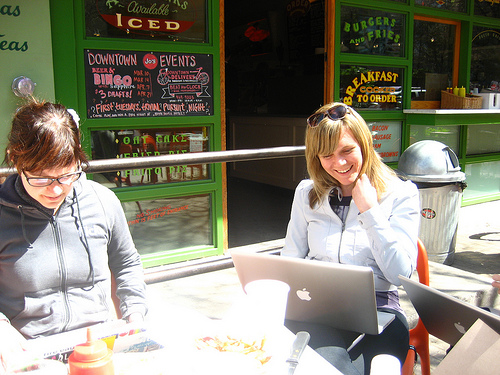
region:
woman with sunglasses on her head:
[308, 107, 365, 267]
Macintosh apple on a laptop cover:
[297, 287, 311, 300]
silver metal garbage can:
[426, 143, 453, 256]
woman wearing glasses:
[18, 112, 74, 316]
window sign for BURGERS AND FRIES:
[344, 15, 401, 46]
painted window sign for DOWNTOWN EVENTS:
[90, 54, 195, 65]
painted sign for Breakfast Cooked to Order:
[351, 72, 396, 102]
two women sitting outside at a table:
[19, 109, 396, 324]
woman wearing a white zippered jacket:
[308, 103, 388, 328]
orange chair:
[410, 325, 427, 367]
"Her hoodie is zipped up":
[7, 120, 143, 333]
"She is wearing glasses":
[8, 117, 102, 222]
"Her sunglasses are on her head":
[292, 83, 409, 252]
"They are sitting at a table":
[5, 82, 497, 373]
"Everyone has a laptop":
[7, 82, 498, 373]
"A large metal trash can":
[403, 123, 490, 267]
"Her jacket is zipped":
[271, 72, 459, 329]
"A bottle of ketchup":
[59, 323, 121, 373]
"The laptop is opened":
[221, 223, 418, 355]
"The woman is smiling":
[283, 103, 424, 258]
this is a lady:
[301, 107, 412, 267]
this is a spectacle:
[306, 106, 348, 118]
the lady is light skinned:
[358, 187, 370, 200]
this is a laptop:
[291, 265, 381, 322]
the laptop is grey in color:
[309, 268, 362, 330]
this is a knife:
[285, 334, 306, 374]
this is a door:
[221, 0, 331, 95]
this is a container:
[246, 277, 286, 319]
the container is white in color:
[258, 299, 276, 314]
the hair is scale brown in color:
[310, 127, 331, 141]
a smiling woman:
[268, 83, 457, 216]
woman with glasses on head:
[4, 113, 110, 216]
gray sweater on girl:
[1, 185, 135, 304]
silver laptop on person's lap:
[227, 253, 415, 341]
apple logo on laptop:
[291, 279, 326, 313]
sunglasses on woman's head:
[286, 111, 371, 138]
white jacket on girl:
[288, 174, 425, 261]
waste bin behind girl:
[408, 135, 478, 267]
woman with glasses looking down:
[16, 94, 121, 239]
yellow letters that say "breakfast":
[340, 68, 410, 110]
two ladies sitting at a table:
[3, 88, 423, 373]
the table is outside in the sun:
[5, 283, 343, 373]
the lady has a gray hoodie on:
[0, 100, 146, 333]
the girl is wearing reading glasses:
[8, 100, 81, 216]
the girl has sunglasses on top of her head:
[300, 100, 371, 185]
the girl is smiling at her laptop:
[305, 101, 385, 198]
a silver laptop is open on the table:
[225, 242, 395, 340]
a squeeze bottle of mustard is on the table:
[67, 325, 112, 371]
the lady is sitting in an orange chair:
[287, 102, 429, 372]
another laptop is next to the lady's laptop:
[297, 269, 499, 351]